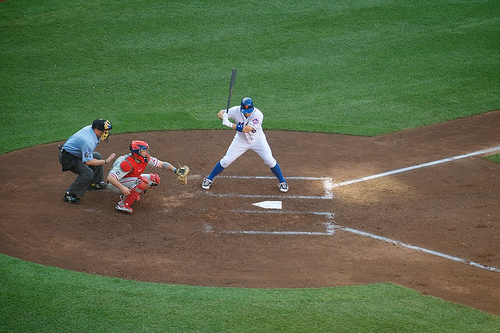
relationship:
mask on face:
[133, 134, 157, 163] [133, 139, 150, 167]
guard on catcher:
[122, 158, 160, 190] [104, 131, 193, 223]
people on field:
[11, 64, 343, 226] [173, 12, 488, 144]